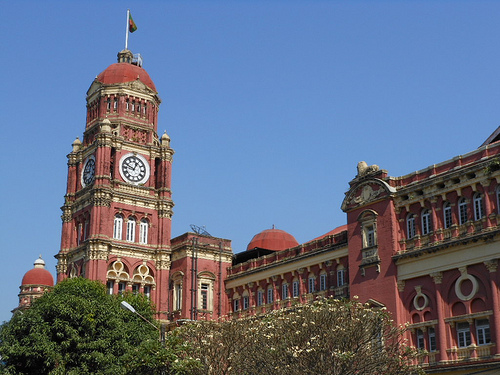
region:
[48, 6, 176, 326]
Very Tall ornate steeple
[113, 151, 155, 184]
Clock in ornate steeple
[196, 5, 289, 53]
Nice clear blue sky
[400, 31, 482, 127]
Nice clear blue sky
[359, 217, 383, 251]
Small arched window of building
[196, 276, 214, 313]
Small arched window of building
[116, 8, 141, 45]
Flag on pole at top of building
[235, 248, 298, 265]
Ornate edge of building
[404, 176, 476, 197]
Ornate edge of building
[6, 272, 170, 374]
Green shrubbery in front of a building.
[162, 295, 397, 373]
White flowers on a bush.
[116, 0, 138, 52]
A flag on top of the building.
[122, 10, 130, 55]
A white flag pole.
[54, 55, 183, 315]
The tallest tower on the building.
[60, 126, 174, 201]
Two clocks on a tower.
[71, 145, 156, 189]
The clock faces are black and white.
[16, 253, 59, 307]
A red dome with a white top.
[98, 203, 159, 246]
Three narrow white windows.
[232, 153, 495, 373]
A red building with narrow windows.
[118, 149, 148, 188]
Fully visible white and black clock.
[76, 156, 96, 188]
A white and black clock on the west side of the tower that's less visible.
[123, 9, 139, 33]
Green flag on top of the clock tower.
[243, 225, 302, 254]
Largest dome hidden by the building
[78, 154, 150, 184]
Two white and black clocks on a tower.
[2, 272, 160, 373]
The largest darked tree top.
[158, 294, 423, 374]
A bunch of tree branches with flowers and no leaves.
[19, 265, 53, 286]
Smaller red dome off to the left.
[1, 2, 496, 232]
Dark blue sky.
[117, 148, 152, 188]
clock on the side of the building.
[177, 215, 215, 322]
Black antenna dish by building.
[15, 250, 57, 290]
domed roof on the building.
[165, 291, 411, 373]
White flowers on trees.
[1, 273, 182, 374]
Tree in the forefront.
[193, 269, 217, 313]
Window in the building.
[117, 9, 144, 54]
Flag on the pole.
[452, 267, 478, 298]
Cement circle on the building.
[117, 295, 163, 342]
Light pole by the tree.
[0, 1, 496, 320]
Blue sky in the background.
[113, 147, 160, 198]
clock on large tower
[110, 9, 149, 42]
flag on top of building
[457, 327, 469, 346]
windows on the window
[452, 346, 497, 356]
balcony attached to building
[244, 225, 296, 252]
dome on top of building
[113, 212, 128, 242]
archway above the window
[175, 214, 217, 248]
satellite on top of building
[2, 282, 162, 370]
green trees in front of building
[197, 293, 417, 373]
white flowers growing from tree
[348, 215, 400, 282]
building made of brick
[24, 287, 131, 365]
a green tree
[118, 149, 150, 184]
a clock on the building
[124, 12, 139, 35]
a flag on top of the building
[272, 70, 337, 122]
the sky is clear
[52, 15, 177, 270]
a tall building